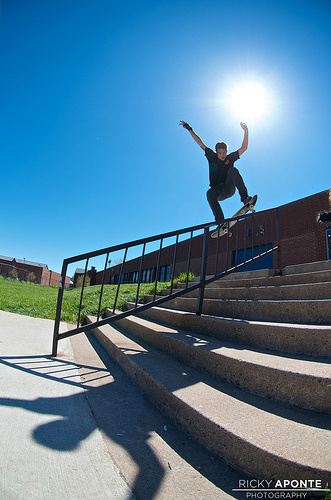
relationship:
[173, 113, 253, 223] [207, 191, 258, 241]
boy on skateboard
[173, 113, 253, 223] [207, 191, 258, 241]
boy riding skateboard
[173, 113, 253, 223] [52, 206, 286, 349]
boy riding on handrail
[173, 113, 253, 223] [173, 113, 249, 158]
boy has arms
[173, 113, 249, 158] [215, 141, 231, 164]
arms over head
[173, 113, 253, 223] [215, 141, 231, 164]
boy has head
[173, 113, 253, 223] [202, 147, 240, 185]
boy wearing shirt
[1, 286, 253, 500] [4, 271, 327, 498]
shadow on ground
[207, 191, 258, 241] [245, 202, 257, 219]
skateboard has wheels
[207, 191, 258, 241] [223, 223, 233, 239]
skateboard has wheels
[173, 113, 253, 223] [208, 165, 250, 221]
boy wearing blue jeans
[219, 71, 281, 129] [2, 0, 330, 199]
sun in sky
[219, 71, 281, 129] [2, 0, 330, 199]
sun shining in sky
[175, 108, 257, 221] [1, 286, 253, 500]
person has shadow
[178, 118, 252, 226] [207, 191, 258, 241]
person jumping with skateboard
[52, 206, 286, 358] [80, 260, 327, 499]
handrail in middle of stairs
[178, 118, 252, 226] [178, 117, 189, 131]
person has hand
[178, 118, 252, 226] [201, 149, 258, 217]
person wearing clothes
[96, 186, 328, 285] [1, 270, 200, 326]
building behind field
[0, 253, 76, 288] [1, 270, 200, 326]
building behind field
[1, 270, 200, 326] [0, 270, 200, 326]
field covered in field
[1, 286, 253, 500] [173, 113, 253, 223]
shadow of boy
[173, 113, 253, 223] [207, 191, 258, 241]
boy jumping on skateboard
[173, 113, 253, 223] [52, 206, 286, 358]
boy going down handrail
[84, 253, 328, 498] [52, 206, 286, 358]
steps next to handrail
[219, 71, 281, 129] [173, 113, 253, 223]
sun above boy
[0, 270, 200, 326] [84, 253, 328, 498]
field next to steps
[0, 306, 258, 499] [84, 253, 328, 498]
sidewalk at base of steps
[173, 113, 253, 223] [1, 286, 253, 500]
boy casts shadow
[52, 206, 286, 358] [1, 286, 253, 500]
handrail casts shadow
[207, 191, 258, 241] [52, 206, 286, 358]
skateboard on handrail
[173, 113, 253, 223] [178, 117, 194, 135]
boy has hand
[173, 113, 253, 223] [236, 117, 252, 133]
boy has hand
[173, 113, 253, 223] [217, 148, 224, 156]
boy has eye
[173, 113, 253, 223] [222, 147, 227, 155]
boy has eye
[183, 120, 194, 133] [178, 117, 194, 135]
protective gear on hand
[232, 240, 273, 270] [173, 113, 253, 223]
door behind boy